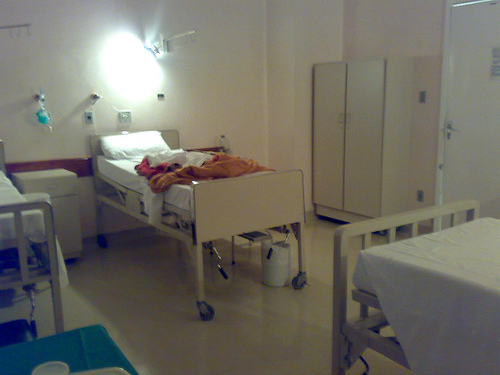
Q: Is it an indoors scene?
A: Yes, it is indoors.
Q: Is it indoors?
A: Yes, it is indoors.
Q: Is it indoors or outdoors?
A: It is indoors.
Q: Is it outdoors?
A: No, it is indoors.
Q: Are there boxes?
A: No, there are no boxes.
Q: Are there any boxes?
A: No, there are no boxes.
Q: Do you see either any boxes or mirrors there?
A: No, there are no boxes or mirrors.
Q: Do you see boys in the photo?
A: No, there are no boys.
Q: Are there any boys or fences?
A: No, there are no boys or fences.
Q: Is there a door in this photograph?
A: Yes, there is a door.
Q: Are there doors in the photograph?
A: Yes, there is a door.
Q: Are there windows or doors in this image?
A: Yes, there is a door.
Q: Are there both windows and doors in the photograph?
A: No, there is a door but no windows.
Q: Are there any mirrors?
A: No, there are no mirrors.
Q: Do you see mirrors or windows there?
A: No, there are no mirrors or windows.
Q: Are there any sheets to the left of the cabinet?
A: Yes, there is a sheet to the left of the cabinet.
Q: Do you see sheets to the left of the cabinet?
A: Yes, there is a sheet to the left of the cabinet.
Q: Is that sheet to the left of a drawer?
A: No, the sheet is to the left of a cabinet.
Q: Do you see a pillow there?
A: Yes, there is a pillow.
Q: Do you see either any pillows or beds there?
A: Yes, there is a pillow.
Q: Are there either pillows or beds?
A: Yes, there is a pillow.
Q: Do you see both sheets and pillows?
A: Yes, there are both a pillow and a sheet.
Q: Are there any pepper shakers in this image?
A: No, there are no pepper shakers.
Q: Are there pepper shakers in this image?
A: No, there are no pepper shakers.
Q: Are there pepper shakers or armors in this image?
A: No, there are no pepper shakers or armors.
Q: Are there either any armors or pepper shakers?
A: No, there are no pepper shakers or armors.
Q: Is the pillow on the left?
A: Yes, the pillow is on the left of the image.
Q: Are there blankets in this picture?
A: Yes, there is a blanket.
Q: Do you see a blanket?
A: Yes, there is a blanket.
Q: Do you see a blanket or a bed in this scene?
A: Yes, there is a blanket.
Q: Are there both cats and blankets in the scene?
A: No, there is a blanket but no cats.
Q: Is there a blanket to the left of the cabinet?
A: Yes, there is a blanket to the left of the cabinet.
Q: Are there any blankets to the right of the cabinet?
A: No, the blanket is to the left of the cabinet.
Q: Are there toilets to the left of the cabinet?
A: No, there is a blanket to the left of the cabinet.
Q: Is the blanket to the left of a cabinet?
A: Yes, the blanket is to the left of a cabinet.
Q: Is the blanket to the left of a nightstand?
A: No, the blanket is to the left of a cabinet.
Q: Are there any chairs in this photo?
A: No, there are no chairs.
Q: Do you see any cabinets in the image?
A: Yes, there is a cabinet.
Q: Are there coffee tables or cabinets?
A: Yes, there is a cabinet.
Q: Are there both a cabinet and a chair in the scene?
A: No, there is a cabinet but no chairs.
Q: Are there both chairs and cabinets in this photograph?
A: No, there is a cabinet but no chairs.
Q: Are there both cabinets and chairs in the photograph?
A: No, there is a cabinet but no chairs.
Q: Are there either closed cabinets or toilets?
A: Yes, there is a closed cabinet.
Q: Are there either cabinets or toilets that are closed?
A: Yes, the cabinet is closed.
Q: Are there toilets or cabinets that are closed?
A: Yes, the cabinet is closed.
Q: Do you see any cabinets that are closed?
A: Yes, there is a closed cabinet.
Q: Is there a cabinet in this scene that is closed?
A: Yes, there is a cabinet that is closed.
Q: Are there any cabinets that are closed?
A: Yes, there is a cabinet that is closed.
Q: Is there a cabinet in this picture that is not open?
A: Yes, there is an closed cabinet.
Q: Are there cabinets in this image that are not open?
A: Yes, there is an closed cabinet.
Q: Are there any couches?
A: No, there are no couches.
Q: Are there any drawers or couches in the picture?
A: No, there are no couches or drawers.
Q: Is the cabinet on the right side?
A: Yes, the cabinet is on the right of the image.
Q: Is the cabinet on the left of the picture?
A: No, the cabinet is on the right of the image.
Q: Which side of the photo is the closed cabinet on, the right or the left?
A: The cabinet is on the right of the image.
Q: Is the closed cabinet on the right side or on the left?
A: The cabinet is on the right of the image.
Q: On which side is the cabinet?
A: The cabinet is on the right of the image.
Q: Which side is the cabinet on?
A: The cabinet is on the right of the image.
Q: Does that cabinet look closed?
A: Yes, the cabinet is closed.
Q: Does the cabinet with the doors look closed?
A: Yes, the cabinet is closed.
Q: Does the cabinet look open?
A: No, the cabinet is closed.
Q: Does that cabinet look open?
A: No, the cabinet is closed.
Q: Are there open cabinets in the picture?
A: No, there is a cabinet but it is closed.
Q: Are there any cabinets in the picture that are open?
A: No, there is a cabinet but it is closed.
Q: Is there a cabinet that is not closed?
A: No, there is a cabinet but it is closed.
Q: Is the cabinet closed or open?
A: The cabinet is closed.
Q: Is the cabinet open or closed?
A: The cabinet is closed.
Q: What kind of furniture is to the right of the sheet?
A: The piece of furniture is a cabinet.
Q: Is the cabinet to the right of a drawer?
A: No, the cabinet is to the right of the sheet.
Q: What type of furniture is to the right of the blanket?
A: The piece of furniture is a cabinet.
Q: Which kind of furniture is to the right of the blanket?
A: The piece of furniture is a cabinet.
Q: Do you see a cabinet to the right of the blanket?
A: Yes, there is a cabinet to the right of the blanket.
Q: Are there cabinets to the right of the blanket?
A: Yes, there is a cabinet to the right of the blanket.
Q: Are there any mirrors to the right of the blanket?
A: No, there is a cabinet to the right of the blanket.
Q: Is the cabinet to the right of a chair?
A: No, the cabinet is to the right of the blanket.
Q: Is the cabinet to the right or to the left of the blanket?
A: The cabinet is to the right of the blanket.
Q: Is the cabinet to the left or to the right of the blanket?
A: The cabinet is to the right of the blanket.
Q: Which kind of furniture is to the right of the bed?
A: The piece of furniture is a cabinet.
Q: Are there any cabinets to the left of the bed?
A: No, the cabinet is to the right of the bed.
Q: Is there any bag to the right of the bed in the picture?
A: No, there is a cabinet to the right of the bed.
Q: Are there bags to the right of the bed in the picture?
A: No, there is a cabinet to the right of the bed.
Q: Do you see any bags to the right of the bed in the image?
A: No, there is a cabinet to the right of the bed.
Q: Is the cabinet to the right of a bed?
A: Yes, the cabinet is to the right of a bed.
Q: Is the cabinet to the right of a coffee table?
A: No, the cabinet is to the right of a bed.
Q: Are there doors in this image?
A: Yes, there are doors.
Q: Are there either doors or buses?
A: Yes, there are doors.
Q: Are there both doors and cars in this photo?
A: No, there are doors but no cars.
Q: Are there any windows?
A: No, there are no windows.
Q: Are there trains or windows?
A: No, there are no windows or trains.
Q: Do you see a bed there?
A: Yes, there is a bed.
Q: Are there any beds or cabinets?
A: Yes, there is a bed.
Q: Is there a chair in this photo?
A: No, there are no chairs.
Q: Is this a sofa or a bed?
A: This is a bed.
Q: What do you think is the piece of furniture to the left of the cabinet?
A: The piece of furniture is a bed.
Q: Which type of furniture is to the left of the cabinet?
A: The piece of furniture is a bed.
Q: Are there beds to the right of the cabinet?
A: No, the bed is to the left of the cabinet.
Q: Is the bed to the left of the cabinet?
A: Yes, the bed is to the left of the cabinet.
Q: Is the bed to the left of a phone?
A: No, the bed is to the left of the cabinet.